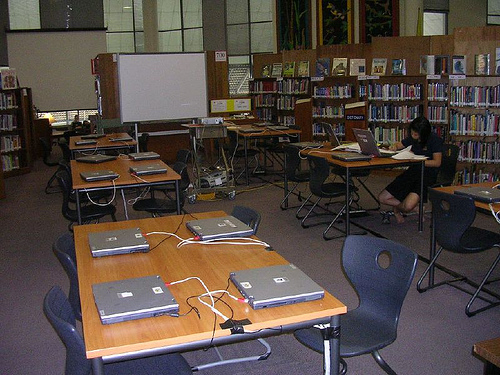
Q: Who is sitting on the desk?
A: Woman in black.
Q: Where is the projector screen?
A: In library.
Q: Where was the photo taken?
A: Library.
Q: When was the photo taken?
A: Daylight.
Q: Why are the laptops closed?
A: Not being used.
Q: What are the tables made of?
A: Wood.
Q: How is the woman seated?
A: With head down.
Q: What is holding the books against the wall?
A: Book shelves.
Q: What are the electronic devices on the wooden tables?
A: Laptop computers.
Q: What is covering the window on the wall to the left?
A: Large white projector screen.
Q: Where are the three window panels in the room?
A: Above the bookshelves on the right.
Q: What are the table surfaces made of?
A: Wood.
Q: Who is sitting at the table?
A: Girl in black shorts and and black tshirt.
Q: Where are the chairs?
A: In front of the wooden tables.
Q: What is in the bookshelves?
A: Books.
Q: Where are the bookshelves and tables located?
A: Library.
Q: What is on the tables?
A: Laptops.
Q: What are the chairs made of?
A: Plastic.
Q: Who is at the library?
A: A girl doing homework.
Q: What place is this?
A: A library.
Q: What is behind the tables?
A: Bookshelves.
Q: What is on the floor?
A: A carpet.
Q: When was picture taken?
A: Daytime.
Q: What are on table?
A: Laptop.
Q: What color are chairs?
A: Grey.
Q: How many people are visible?
A: One.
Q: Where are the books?
A: On shelves.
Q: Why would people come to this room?
A: To read.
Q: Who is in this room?
A: A lady.